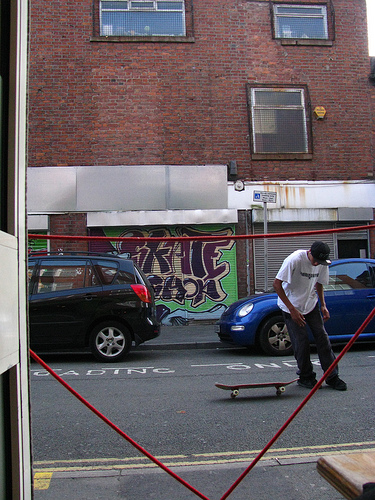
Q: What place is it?
A: It is a street.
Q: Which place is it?
A: It is a street.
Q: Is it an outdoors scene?
A: Yes, it is outdoors.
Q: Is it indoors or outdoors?
A: It is outdoors.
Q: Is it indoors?
A: No, it is outdoors.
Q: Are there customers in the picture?
A: No, there are no customers.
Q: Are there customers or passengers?
A: No, there are no customers or passengers.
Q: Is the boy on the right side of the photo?
A: Yes, the boy is on the right of the image.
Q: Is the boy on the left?
A: No, the boy is on the right of the image.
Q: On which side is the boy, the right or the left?
A: The boy is on the right of the image.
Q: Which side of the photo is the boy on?
A: The boy is on the right of the image.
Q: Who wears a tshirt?
A: The boy wears a tshirt.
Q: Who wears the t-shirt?
A: The boy wears a tshirt.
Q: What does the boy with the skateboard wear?
A: The boy wears a t-shirt.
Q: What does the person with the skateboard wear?
A: The boy wears a t-shirt.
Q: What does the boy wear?
A: The boy wears a t-shirt.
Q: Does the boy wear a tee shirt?
A: Yes, the boy wears a tee shirt.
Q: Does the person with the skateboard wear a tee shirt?
A: Yes, the boy wears a tee shirt.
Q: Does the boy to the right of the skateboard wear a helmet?
A: No, the boy wears a tee shirt.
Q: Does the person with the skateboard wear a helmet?
A: No, the boy wears a tee shirt.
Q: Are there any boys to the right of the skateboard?
A: Yes, there is a boy to the right of the skateboard.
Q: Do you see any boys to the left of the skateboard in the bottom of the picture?
A: No, the boy is to the right of the skateboard.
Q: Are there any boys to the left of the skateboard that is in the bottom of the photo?
A: No, the boy is to the right of the skateboard.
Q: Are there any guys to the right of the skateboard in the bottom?
A: No, there is a boy to the right of the skateboard.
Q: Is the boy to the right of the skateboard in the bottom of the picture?
A: Yes, the boy is to the right of the skateboard.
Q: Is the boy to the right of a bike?
A: No, the boy is to the right of the skateboard.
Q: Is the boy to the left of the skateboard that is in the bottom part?
A: No, the boy is to the right of the skateboard.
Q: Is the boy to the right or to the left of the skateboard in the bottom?
A: The boy is to the right of the skateboard.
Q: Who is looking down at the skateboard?
A: The boy is looking down at the skateboard.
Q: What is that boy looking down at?
A: The boy is looking down at the skateboard.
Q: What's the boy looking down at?
A: The boy is looking down at the skateboard.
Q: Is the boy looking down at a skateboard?
A: Yes, the boy is looking down at a skateboard.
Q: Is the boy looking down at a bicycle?
A: No, the boy is looking down at a skateboard.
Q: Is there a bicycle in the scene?
A: No, there are no bicycles.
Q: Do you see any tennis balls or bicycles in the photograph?
A: No, there are no bicycles or tennis balls.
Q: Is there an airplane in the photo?
A: No, there are no airplanes.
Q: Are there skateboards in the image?
A: Yes, there is a skateboard.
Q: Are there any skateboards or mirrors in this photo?
A: Yes, there is a skateboard.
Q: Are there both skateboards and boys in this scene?
A: Yes, there are both a skateboard and a boy.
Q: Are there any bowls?
A: No, there are no bowls.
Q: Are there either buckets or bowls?
A: No, there are no bowls or buckets.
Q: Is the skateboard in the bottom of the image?
A: Yes, the skateboard is in the bottom of the image.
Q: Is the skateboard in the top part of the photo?
A: No, the skateboard is in the bottom of the image.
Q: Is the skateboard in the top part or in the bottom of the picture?
A: The skateboard is in the bottom of the image.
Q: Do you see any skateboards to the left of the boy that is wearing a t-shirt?
A: Yes, there is a skateboard to the left of the boy.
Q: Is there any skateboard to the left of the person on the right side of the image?
A: Yes, there is a skateboard to the left of the boy.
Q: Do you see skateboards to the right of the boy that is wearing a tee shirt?
A: No, the skateboard is to the left of the boy.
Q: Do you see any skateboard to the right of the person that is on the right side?
A: No, the skateboard is to the left of the boy.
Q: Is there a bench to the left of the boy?
A: No, there is a skateboard to the left of the boy.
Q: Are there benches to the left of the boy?
A: No, there is a skateboard to the left of the boy.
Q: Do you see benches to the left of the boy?
A: No, there is a skateboard to the left of the boy.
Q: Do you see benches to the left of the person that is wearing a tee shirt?
A: No, there is a skateboard to the left of the boy.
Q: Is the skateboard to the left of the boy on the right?
A: Yes, the skateboard is to the left of the boy.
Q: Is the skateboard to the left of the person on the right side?
A: Yes, the skateboard is to the left of the boy.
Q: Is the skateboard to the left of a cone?
A: No, the skateboard is to the left of the boy.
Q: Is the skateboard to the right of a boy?
A: No, the skateboard is to the left of a boy.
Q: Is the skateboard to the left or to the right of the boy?
A: The skateboard is to the left of the boy.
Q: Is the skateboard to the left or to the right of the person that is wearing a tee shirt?
A: The skateboard is to the left of the boy.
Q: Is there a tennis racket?
A: No, there are no rackets.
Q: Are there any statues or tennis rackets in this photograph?
A: No, there are no tennis rackets or statues.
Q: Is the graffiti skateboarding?
A: Yes, the graffiti is skateboarding.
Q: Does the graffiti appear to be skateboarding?
A: Yes, the graffiti is skateboarding.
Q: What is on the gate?
A: The graffiti is on the gate.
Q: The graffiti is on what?
A: The graffiti is on the gate.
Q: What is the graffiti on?
A: The graffiti is on the gate.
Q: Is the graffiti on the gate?
A: Yes, the graffiti is on the gate.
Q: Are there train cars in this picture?
A: No, there are no train cars.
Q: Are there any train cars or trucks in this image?
A: No, there are no train cars or trucks.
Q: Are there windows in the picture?
A: Yes, there is a window.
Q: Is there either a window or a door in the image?
A: Yes, there is a window.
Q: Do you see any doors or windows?
A: Yes, there is a window.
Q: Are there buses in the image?
A: No, there are no buses.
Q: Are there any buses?
A: No, there are no buses.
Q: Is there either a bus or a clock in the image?
A: No, there are no buses or clocks.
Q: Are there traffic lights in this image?
A: No, there are no traffic lights.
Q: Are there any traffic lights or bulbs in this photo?
A: No, there are no traffic lights or bulbs.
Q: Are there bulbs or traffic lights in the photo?
A: No, there are no traffic lights or bulbs.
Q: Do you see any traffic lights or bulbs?
A: No, there are no traffic lights or bulbs.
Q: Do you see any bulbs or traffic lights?
A: No, there are no traffic lights or bulbs.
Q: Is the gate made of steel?
A: Yes, the gate is made of steel.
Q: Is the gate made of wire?
A: No, the gate is made of steel.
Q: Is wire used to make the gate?
A: No, the gate is made of steel.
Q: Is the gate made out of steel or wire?
A: The gate is made of steel.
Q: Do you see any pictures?
A: No, there are no pictures.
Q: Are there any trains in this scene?
A: No, there are no trains.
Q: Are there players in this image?
A: No, there are no players.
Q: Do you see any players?
A: No, there are no players.